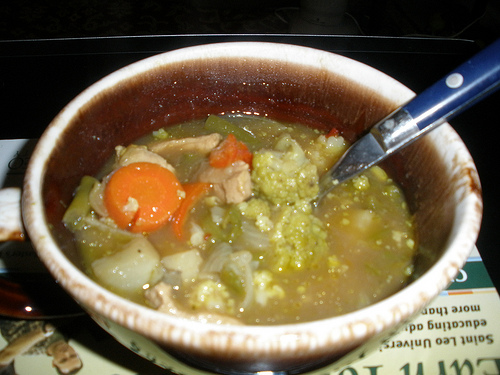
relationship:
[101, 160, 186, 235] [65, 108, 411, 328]
orange carrot in soup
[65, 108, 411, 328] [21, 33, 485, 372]
soup in soup bowl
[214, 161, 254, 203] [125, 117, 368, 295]
chunk in soup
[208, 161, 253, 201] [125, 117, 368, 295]
chicken in soup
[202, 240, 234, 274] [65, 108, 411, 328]
onion in soup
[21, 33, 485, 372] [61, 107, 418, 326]
soup bowl of food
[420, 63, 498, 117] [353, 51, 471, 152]
dot on spoon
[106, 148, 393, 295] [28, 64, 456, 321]
vegetables in soup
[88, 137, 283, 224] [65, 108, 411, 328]
carrots in soup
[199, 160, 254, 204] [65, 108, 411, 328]
meat in soup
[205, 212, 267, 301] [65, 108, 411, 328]
onions in soup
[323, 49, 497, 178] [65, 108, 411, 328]
spoon in soup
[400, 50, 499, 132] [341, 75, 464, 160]
handle on spoon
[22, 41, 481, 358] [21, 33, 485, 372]
rim on soup bowl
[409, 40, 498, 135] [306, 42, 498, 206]
handle on spoon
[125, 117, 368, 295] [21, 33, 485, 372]
soup in soup bowl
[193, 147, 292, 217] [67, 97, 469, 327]
chicken chunk in soup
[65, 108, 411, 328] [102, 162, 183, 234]
soup with carrot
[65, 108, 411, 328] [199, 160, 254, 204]
soup with meat